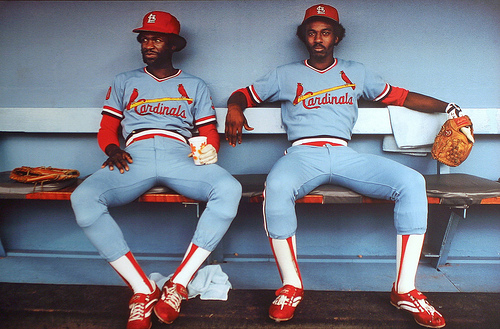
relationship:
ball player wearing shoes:
[223, 4, 476, 326] [121, 281, 450, 325]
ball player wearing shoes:
[67, 2, 241, 327] [121, 281, 450, 325]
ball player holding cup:
[67, 2, 241, 327] [183, 131, 216, 165]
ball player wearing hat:
[67, 2, 241, 327] [131, 10, 179, 35]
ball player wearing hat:
[223, 4, 476, 326] [302, 4, 340, 26]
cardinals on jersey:
[301, 90, 352, 110] [244, 56, 392, 144]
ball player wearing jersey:
[67, 2, 241, 327] [88, 64, 232, 154]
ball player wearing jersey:
[223, 4, 476, 326] [233, 54, 407, 153]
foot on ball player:
[247, 262, 322, 327] [223, 4, 476, 326]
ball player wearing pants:
[67, 2, 241, 327] [54, 137, 242, 278]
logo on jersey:
[289, 83, 361, 115] [240, 51, 392, 156]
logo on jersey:
[121, 86, 196, 129] [95, 54, 212, 152]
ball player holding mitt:
[223, 4, 476, 326] [429, 112, 479, 168]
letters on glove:
[290, 81, 368, 111] [432, 101, 485, 146]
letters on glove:
[124, 94, 196, 124] [432, 101, 485, 146]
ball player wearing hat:
[223, 4, 476, 326] [298, 4, 343, 31]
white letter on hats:
[145, 4, 326, 24] [130, 2, 342, 37]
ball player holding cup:
[67, 2, 241, 327] [183, 126, 209, 167]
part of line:
[286, 234, 299, 294] [288, 258, 305, 288]